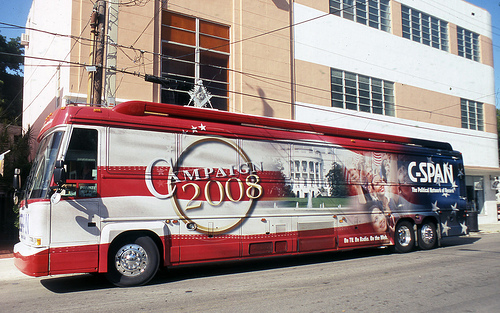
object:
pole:
[85, 0, 107, 108]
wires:
[0, 20, 499, 128]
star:
[446, 201, 461, 214]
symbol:
[183, 79, 214, 110]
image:
[275, 139, 353, 210]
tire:
[393, 219, 417, 254]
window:
[197, 78, 231, 97]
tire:
[413, 221, 437, 249]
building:
[18, 0, 499, 226]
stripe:
[294, 59, 496, 134]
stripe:
[290, 2, 496, 108]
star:
[455, 219, 468, 235]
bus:
[13, 100, 477, 289]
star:
[429, 199, 441, 214]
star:
[440, 191, 452, 200]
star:
[437, 221, 450, 236]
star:
[456, 165, 463, 178]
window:
[60, 127, 102, 182]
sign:
[404, 160, 458, 194]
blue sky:
[0, 0, 34, 76]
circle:
[164, 136, 259, 237]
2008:
[180, 175, 264, 212]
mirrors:
[51, 160, 66, 187]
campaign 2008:
[143, 157, 266, 211]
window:
[383, 109, 395, 118]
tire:
[101, 230, 161, 288]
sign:
[141, 137, 264, 239]